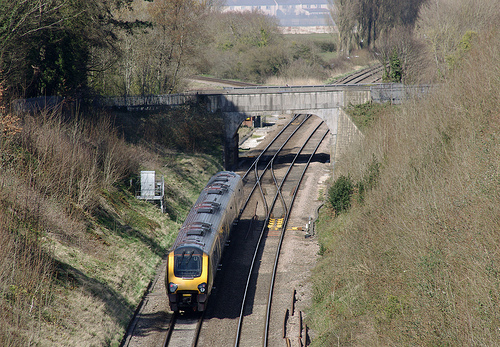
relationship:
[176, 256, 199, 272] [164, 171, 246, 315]
windshield on train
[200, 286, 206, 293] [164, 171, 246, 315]
light on train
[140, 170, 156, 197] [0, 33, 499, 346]
box on ground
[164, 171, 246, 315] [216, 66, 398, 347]
train driving on track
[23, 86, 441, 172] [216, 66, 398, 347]
bridge over track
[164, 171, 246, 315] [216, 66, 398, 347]
train on track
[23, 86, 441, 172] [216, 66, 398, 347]
bridge above track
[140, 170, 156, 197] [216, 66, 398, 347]
box next to track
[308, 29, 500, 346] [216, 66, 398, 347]
hill next to track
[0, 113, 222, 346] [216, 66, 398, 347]
weeds next to track